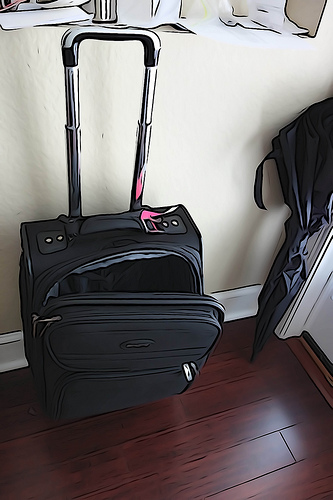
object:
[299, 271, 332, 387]
door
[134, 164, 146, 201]
reflection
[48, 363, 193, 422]
black zip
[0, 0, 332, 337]
wall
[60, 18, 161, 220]
handle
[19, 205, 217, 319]
top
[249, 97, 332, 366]
black umbrella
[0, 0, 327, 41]
picture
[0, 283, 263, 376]
molding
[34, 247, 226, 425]
main compartment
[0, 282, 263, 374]
baseboards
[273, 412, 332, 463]
floorboards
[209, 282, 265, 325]
floor board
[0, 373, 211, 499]
shadow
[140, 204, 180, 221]
label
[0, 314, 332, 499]
floor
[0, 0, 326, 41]
painting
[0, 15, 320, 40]
edge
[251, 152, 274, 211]
strap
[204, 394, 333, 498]
light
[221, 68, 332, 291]
shadow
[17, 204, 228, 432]
bag